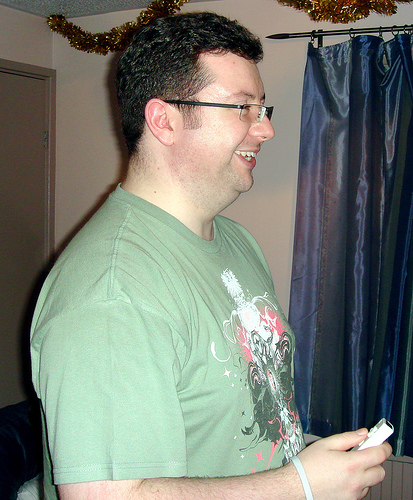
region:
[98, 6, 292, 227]
A man is smiling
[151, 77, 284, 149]
The man is wearing glasses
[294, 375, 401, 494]
Wii controller in the man's hand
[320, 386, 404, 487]
White game controller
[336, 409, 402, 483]
White controller in man's hand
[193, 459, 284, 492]
Hair on a man's arm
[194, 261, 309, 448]
Design on the man's shirt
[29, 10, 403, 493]
The man is playing a game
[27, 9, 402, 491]
The man is playing a video game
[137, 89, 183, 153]
Ear of a man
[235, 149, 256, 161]
White teeth in a man's mouth.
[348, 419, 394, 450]
A white and black Wii remote.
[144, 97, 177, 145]
A right ear of a man.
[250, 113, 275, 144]
Nose on a man's face.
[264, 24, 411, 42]
A black curtain rod.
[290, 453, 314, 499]
Grey strap around a man's wrist.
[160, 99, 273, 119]
Thin black framed glasses.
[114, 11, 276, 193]
Head of a man.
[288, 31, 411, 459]
A shiny blue curtain.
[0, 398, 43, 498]
A blue couch back.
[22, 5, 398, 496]
A man is playing a video game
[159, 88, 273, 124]
A pair of glasses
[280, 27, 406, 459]
The curtains are blue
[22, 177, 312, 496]
A green short sleeved shirt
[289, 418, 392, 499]
white Wii controller and wrist strap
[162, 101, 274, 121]
a pair of eye glasses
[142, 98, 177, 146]
a person's right ear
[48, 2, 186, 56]
a gold foil tinsel garland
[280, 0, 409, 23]
a gold foil tinsel garland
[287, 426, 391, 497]
a person's right hand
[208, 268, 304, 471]
design on a green shirt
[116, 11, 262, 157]
a man's hair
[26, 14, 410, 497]
this is a man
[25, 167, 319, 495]
man wearing a green shirt